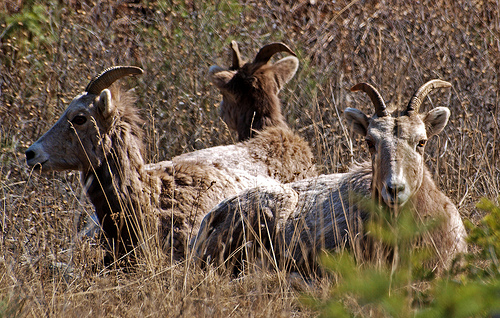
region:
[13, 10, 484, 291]
rams on the ground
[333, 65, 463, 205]
this ram has two horns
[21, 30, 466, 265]
three rams in the picture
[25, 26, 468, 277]
these rams are brown and white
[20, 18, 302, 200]
these two rams look like they are connected together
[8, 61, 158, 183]
this lamb is facing left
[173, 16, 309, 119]
this ram is looking backward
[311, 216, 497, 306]
a patch of green vegetation in the picture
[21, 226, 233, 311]
dead brown grass in the scene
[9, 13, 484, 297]
these are herd animals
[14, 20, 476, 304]
three goats lying on the ground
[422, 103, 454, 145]
right ear of goat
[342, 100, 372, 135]
left ear of goat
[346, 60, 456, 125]
horn of goat are curved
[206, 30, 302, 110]
horns over head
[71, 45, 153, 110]
horns over head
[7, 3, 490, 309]
a field with dry grass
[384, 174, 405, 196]
nose of goat is black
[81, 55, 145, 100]
the horns are curve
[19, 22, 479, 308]
goats are brown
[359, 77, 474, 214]
the head of a goat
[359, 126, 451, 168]
the eyes of a goat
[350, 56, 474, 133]
the horns of a goat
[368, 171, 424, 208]
the nose of a goat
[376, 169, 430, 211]
the mouth of a goat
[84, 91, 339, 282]
the body of a goat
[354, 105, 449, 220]
the face of a goat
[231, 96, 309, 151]
the neck of a goat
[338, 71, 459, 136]
the ears of a goat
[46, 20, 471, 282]
goats laying down in a field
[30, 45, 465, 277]
animals laying in a field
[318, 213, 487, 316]
a branch of a tree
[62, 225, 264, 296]
weeds under the animals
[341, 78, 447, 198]
the face of the animal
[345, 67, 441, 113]
the horns of the animal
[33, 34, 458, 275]
three animals laying down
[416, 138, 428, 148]
the eye of the animal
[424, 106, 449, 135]
the ear of the animal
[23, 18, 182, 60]
bushes in the background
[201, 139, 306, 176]
the fur of the animal